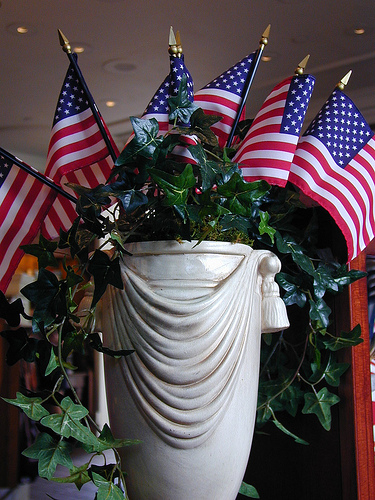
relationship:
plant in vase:
[154, 159, 192, 176] [93, 241, 291, 500]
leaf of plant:
[91, 195, 152, 225] [154, 159, 192, 176]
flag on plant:
[168, 71, 186, 74] [154, 159, 192, 176]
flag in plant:
[168, 71, 186, 74] [154, 159, 192, 176]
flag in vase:
[168, 71, 186, 74] [241, 282, 255, 354]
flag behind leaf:
[168, 71, 186, 74] [91, 195, 152, 225]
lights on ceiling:
[12, 16, 33, 41] [214, 18, 237, 30]